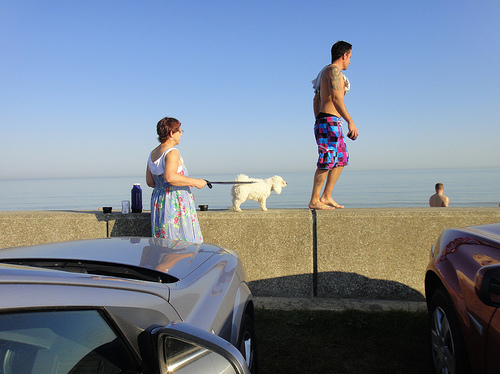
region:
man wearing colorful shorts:
[307, 39, 358, 214]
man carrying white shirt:
[309, 40, 357, 210]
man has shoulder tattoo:
[312, 37, 357, 209]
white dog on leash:
[205, 172, 283, 208]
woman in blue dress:
[144, 121, 203, 243]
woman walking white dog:
[142, 118, 288, 243]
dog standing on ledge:
[222, 170, 294, 219]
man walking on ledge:
[306, 37, 359, 212]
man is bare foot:
[305, 39, 358, 212]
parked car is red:
[432, 225, 496, 367]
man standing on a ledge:
[279, 5, 376, 234]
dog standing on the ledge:
[217, 164, 301, 223]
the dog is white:
[225, 157, 302, 224]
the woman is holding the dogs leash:
[110, 99, 210, 234]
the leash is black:
[177, 172, 259, 192]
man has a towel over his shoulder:
[290, 58, 363, 103]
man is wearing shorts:
[297, 107, 360, 186]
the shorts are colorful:
[288, 100, 374, 172]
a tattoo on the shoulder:
[313, 59, 350, 100]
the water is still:
[357, 150, 499, 207]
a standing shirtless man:
[311, 40, 359, 210]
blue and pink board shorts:
[311, 113, 350, 171]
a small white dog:
[231, 171, 286, 210]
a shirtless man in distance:
[428, 181, 448, 208]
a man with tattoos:
[311, 38, 358, 210]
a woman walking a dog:
[145, 115, 288, 245]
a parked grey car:
[0, 234, 264, 371]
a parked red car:
[415, 225, 497, 371]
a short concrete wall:
[4, 209, 497, 308]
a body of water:
[0, 167, 499, 208]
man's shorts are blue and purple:
[276, 101, 393, 192]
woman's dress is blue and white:
[140, 133, 205, 252]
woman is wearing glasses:
[155, 106, 184, 141]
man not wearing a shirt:
[293, 46, 358, 117]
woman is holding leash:
[106, 91, 251, 196]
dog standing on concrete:
[196, 156, 301, 233]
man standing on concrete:
[313, 18, 393, 213]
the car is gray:
[1, 172, 253, 370]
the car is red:
[399, 194, 497, 369]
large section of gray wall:
[365, 205, 483, 222]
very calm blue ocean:
[9, 179, 80, 194]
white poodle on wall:
[227, 165, 290, 210]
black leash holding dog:
[201, 175, 262, 187]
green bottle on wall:
[117, 175, 148, 218]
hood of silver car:
[43, 233, 229, 278]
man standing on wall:
[299, 26, 380, 164]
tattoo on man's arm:
[325, 66, 345, 98]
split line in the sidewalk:
[288, 204, 336, 305]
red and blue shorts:
[306, 109, 358, 180]